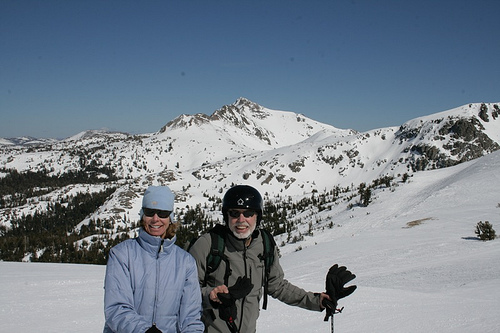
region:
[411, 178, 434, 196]
part of a slope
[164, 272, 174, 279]
part of a jacket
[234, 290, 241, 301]
part of a glove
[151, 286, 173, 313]
part of a zipper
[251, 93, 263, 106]
tip of a mountain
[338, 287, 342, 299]
part of a glove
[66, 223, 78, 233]
part of a forest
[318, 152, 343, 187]
edge of a slope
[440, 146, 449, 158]
part of a mountain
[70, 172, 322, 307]
the skiers are smiling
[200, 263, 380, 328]
the man is holding his gloves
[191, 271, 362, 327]
the man is holding ski poles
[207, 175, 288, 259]
the man is wearing a black helmet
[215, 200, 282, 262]
the man is wearing black sunglasses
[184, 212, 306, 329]
the man is wearing a backpack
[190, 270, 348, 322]
the man's gloves are black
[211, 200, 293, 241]
the man has white facial hair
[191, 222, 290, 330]
the man is wearing a brown jacket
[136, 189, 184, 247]
the woman is smiling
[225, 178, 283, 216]
Person wearing black helmet.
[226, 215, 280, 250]
Person has gray beard.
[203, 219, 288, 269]
Green straps on man's shoulders.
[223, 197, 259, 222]
Sunglasses on man's face.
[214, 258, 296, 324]
Man wearing gray coat.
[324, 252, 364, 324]
Man holding black glove.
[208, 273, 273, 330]
Man holding black glove.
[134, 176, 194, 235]
Person wearing blue hat.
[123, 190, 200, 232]
Sunglasses on person's face.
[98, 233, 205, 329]
Person wearing blue coat.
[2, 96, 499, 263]
Mountains covered with snow.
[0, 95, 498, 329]
White snow covering the mountains and the ground.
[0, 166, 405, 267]
Evergreen trees.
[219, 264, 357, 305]
A black pair of ski gloves.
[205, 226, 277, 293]
Green and black backpack straps.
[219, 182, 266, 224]
A black ski helmet.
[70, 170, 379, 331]
Two men skiing.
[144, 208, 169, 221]
A pair of black sunglasses.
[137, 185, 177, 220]
A grey tobogan.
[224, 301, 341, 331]
Ski poles.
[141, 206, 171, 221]
a person wearing glasses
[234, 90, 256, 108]
the peak of the mountain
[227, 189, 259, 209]
a black helmet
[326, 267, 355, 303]
a person is carrying gloves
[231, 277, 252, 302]
the gloves are black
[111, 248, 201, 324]
the jacket is blue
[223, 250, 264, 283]
a grey sweatshirt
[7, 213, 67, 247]
trees on the mountain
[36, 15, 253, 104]
the sky is clear and blue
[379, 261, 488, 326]
the snow is white